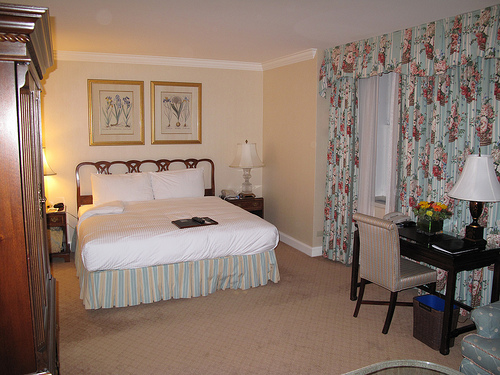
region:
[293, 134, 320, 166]
edge fo a all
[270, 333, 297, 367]
part of a floor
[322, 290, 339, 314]
part of a floor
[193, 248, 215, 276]
par of a bed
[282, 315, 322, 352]
part of a floor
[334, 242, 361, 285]
part of a stand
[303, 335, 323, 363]
part of a floor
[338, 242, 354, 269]
part of a curtain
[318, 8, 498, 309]
"Floral print curtains"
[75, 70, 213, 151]
"Two pictures on the wall"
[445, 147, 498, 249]
"A lamp"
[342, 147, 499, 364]
"The lamp is on the table"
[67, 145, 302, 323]
"A bed"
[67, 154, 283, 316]
"Two pillows are on the bed"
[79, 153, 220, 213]
"The pillows are white"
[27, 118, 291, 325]
"There are lamps on both sides of the bed"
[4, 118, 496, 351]
"One of out three lamps are on"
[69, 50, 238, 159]
"The framed pictures are side by side"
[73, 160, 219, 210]
A wooden headboard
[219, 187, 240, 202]
A telephone on a nightstand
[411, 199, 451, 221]
Flowers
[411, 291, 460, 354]
A wicker trash bin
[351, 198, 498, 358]
A dark colored desk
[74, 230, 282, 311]
A blue and beige bed skirt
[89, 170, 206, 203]
Two white pillows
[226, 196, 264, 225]
A nightstand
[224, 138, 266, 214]
A lamp on a nightstand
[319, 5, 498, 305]
Blue floral curtains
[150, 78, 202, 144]
art picture framed and hanging on a wall above a bed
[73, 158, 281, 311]
bed with head board covered in white inside a bedroom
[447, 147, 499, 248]
lamp on top of a desk inside a bedroom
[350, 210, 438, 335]
chair found at a work desk inside a bedroom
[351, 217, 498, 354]
desk found inside a bedroom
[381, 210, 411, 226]
off white color phone sitting on top of a desk inside a bedroom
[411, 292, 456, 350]
small trash can lined with a bold blue color on the floor under a desk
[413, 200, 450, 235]
flowers inside a pot sitting on a desk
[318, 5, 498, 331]
large curtains covering a bedroom window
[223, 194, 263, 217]
wooden nightstand holding a lamp directly near a bed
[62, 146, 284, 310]
made bed in room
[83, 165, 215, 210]
two pillows on bed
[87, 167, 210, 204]
two pillows are white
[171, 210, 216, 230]
book sitting on bed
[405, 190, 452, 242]
flowers are on table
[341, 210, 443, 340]
chair pushed under table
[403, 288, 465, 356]
wicker trash can under table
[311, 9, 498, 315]
flowers on curtain hanging on window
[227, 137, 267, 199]
lamp sitting on end table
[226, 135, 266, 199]
lamp on end table is white